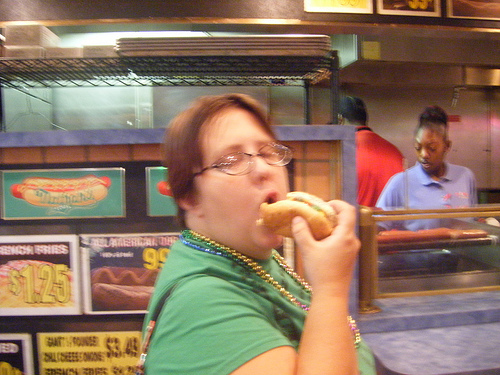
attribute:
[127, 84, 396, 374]
person — eating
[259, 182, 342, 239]
hotdog — half eaten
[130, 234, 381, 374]
shirt — green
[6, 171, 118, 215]
sign — hot dog, decorative, green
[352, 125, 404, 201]
shirt — red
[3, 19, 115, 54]
sheets — stack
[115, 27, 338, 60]
trays — long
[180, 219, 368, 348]
beads — multi colored, metallic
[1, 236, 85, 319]
sign — colored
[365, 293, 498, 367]
counter — blue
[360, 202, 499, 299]
partition — wood, glass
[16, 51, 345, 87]
shelving — wire mesh